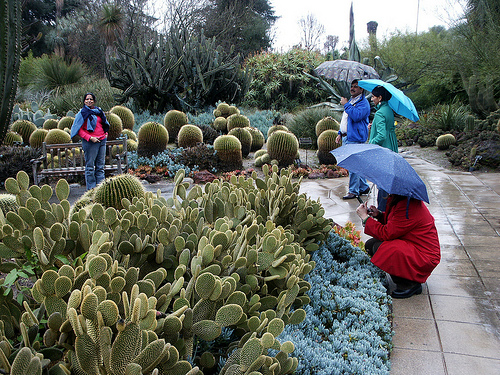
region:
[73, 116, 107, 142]
a red shirt on a woman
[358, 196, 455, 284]
a red coat on a person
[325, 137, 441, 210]
a navy umbrella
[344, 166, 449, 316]
a person squatting to look at pants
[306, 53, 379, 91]
a gray umbrella in a man's hand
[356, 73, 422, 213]
a woman holding a blue umbrella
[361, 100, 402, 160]
a green jacket on a woman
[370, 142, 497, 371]
a square concrete paved walkway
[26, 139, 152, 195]
a bench among the plants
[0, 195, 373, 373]
a garden of plants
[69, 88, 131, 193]
lady with pink shirt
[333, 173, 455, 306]
person in red coat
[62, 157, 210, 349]
large green cactus garden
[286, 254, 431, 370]
blue flowers along walkway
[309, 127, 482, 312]
person holding blue umbrella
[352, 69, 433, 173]
lady wearing turquoise coat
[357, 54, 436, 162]
lady holding blue umbrella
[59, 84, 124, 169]
person wearing blue jeans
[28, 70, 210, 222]
person standing by bench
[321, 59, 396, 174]
guy wearing blue jacket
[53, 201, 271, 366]
group of catus plants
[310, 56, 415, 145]
two people under umbrellas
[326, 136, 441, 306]
person with blue umbrella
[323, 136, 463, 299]
person wearing a red coat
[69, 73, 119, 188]
woman with pink shirt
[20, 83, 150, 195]
woman standing next to bench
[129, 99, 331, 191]
catus plants on display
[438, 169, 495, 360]
wet cement sidewalk squares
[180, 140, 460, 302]
person looking at catus in rain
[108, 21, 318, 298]
catus garden display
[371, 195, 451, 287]
the coat is red in color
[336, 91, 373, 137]
the coat is blue in color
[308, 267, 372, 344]
the flowers are light blue in color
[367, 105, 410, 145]
the coat is tourquiose in color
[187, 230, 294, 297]
the cactus is a light green in color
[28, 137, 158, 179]
the bench is a grey brown color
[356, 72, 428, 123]
the umbrella is tourquious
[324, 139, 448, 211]
the umbrella is blue in color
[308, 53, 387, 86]
the umbrella is grey in color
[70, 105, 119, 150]
the coat is light and dark blue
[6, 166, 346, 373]
Smaller cactuses here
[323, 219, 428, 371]
Flowers below the cactuses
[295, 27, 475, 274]
These people have umbrellas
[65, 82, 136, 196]
She is looking at the plants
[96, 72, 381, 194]
Bush catus in the back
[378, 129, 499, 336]
This road is made of marbles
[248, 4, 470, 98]
It is sunny outside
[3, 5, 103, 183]
A taller cactus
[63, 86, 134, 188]
She is wearing a pink shirt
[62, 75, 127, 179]
She has black hair